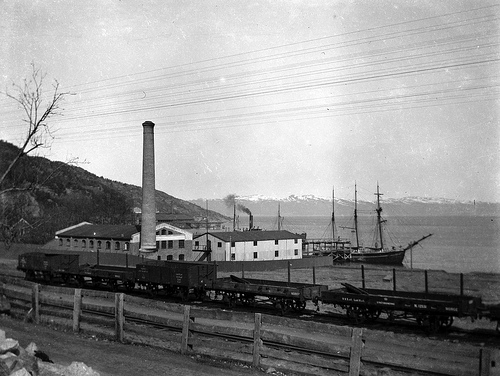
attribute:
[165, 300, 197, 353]
post — fence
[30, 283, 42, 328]
post — fence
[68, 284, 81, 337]
post — fence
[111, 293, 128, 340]
post — fence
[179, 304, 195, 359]
post — fence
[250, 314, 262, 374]
post — fence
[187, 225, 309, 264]
building — long, white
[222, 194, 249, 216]
smoke — black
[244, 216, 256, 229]
smoke stack — small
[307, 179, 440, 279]
boat — large, sailless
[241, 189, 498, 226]
mountains — snow-capped, distant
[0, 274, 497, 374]
wooden fence — short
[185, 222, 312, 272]
factory — white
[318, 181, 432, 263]
vessel — large, old world, sailing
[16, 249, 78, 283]
car — box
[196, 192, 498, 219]
mountains — snowcapped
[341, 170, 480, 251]
mountain — snow-capped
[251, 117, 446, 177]
clouds — white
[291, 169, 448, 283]
sailboat — black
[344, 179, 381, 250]
mast — tall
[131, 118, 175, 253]
tower — large, brick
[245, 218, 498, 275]
ocean water — calm, grey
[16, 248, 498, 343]
train — black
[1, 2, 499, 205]
sky — sunlit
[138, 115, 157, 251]
smokestack — stone